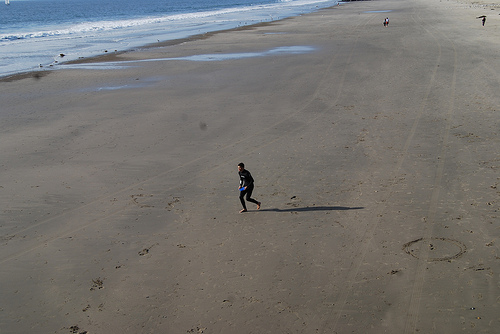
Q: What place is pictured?
A: It is a beach.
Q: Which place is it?
A: It is a beach.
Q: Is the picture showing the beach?
A: Yes, it is showing the beach.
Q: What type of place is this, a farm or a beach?
A: It is a beach.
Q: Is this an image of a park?
A: No, the picture is showing a beach.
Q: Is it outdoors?
A: Yes, it is outdoors.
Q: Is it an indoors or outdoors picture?
A: It is outdoors.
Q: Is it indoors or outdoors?
A: It is outdoors.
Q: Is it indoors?
A: No, it is outdoors.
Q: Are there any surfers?
A: No, there are no surfers.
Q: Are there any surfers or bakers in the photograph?
A: No, there are no surfers or bakers.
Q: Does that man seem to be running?
A: Yes, the man is running.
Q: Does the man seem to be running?
A: Yes, the man is running.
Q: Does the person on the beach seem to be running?
A: Yes, the man is running.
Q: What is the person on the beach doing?
A: The man is running.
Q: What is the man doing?
A: The man is running.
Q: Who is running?
A: The man is running.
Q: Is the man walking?
A: No, the man is running.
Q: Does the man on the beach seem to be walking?
A: No, the man is running.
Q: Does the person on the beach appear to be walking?
A: No, the man is running.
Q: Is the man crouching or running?
A: The man is running.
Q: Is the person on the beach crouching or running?
A: The man is running.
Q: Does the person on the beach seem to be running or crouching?
A: The man is running.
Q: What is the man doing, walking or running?
A: The man is running.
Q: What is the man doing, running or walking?
A: The man is running.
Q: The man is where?
A: The man is on the beach.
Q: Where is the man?
A: The man is on the beach.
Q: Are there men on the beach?
A: Yes, there is a man on the beach.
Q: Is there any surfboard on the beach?
A: No, there is a man on the beach.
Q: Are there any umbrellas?
A: No, there are no umbrellas.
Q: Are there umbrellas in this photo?
A: No, there are no umbrellas.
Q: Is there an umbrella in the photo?
A: No, there are no umbrellas.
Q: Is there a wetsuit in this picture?
A: Yes, there is a wetsuit.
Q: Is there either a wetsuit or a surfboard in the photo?
A: Yes, there is a wetsuit.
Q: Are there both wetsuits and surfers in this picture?
A: No, there is a wetsuit but no surfers.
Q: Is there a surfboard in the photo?
A: No, there are no surfboards.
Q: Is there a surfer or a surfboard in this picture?
A: No, there are no surfboards or surfers.